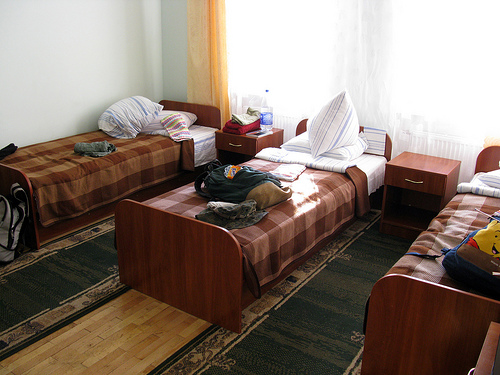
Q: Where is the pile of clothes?
A: On the bed.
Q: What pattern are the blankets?
A: Plaid.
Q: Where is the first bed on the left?
A: In the corner of the room.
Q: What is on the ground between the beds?
A: Rugs.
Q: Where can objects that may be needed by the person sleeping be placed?
A: On the night stands.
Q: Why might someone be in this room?
A: To sleep.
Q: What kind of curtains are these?
A: Sheer.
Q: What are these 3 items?
A: Beds.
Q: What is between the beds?
A: Nightstands.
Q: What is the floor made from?
A: Wooden.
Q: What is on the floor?
A: Rugs.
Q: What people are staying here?
A: Students.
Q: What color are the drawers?
A: Brown.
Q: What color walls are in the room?
A: White.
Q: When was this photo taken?
A: Daytime.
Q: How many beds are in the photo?
A: Three.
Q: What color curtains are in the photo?
A: White.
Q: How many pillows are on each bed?
A: Two.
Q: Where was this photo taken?
A: A bedroom.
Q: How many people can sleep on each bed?
A: One.